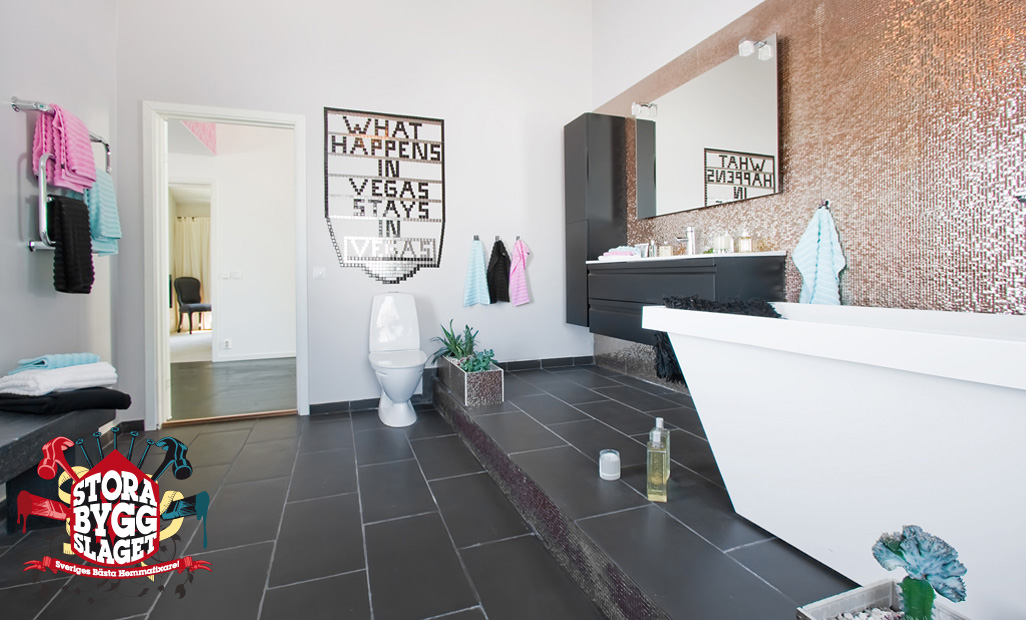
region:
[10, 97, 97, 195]
a large purple towel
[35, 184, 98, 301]
a large black towel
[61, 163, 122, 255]
a large blue towel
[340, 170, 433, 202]
the word vegas on a sign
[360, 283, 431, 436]
a small white toilet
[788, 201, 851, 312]
a large blue towel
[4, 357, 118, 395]
a large white towel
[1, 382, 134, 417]
a large black towel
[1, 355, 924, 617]
black floor tile with white lines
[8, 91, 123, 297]
Pink, blue and black towels hanging on a metal rack.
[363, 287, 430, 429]
A white porcelain toilet.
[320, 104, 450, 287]
A sign says "What happens in vegas, stays in vegas".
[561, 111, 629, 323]
A shiny black cabinet is mounted on the wall.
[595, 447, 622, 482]
A candle in a glass holder.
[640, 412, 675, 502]
Two bottles of shampoo.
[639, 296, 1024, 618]
A large white bath tub.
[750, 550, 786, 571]
tile on the floor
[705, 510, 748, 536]
tile on the floor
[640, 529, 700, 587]
tile on the floor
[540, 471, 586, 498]
tile on the floor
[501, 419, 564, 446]
tile on the floor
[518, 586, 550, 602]
tile on the floor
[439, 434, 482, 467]
tile on the floor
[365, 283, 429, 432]
a white toilet bowl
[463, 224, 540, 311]
three hand towels hanging on a wall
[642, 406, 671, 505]
two clear bottles on the floor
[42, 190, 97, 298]
a black towel on a rack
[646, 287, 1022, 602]
a square white bathtub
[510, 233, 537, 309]
a pink towel hanging on a wall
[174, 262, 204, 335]
a black chair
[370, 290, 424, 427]
the toilet is white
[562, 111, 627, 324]
the cabinet is black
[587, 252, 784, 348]
the vanity is black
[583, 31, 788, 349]
the mirror above the vanity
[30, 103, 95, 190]
the towel is pink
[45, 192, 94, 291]
the towel is black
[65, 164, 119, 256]
the towel is blue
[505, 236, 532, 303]
the hand towel is pink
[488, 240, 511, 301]
the hand towel is blue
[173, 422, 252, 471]
a tile in a floor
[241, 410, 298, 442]
a tile in a floor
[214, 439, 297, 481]
a tile in a floor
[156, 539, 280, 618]
a tile in a floor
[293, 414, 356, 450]
a tile in a floor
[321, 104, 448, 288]
A large sign posted above a toilet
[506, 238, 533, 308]
A pink hand towel hanging on wall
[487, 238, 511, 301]
a black hand towel hanging on wall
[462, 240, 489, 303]
a light blue hand towel hanging on wall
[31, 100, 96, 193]
a pink bath towel hanging on rack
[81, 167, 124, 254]
a light blue bath towel hanging on rack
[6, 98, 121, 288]
bath towels hanging on rack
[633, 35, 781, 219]
a large frameless mirror in bathroom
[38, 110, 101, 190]
The towel is pink.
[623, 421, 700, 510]
Two bottles on the floor.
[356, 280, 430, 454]
A white toilet under the writing.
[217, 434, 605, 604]
The floor is brown tiled.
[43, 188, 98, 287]
The towel is black.